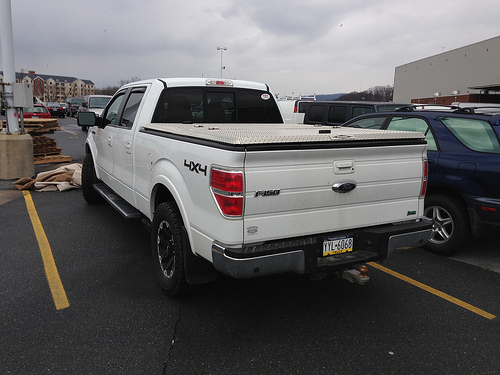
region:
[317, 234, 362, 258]
License plate on pickup truck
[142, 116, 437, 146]
Steel bed cover on pickup truck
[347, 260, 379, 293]
Trailer hitch on pickup truck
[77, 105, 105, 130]
Rearview mirror on pickup truck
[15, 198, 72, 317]
Yellow lines painted on the street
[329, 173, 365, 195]
Manufacturer emblem of a pickup truck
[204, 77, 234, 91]
Third brake light on the pickup truck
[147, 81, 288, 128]
Tinted rear window on a pickup truck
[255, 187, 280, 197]
Model designation on a pickup truck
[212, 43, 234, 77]
Outdoor lighting in the far distance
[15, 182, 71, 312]
Yellow painted line on the ground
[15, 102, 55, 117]
Red colored car in the distance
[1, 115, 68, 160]
Wooden pallets on the ground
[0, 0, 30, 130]
Grey colored light pole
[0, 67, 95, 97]
Light brown, red, and black apartment complex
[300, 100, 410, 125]
Black colored van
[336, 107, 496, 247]
Blue and black colored car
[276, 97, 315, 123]
White colored van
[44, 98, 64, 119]
Black colored car in the distance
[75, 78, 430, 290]
White, black, and silver colored truck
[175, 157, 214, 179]
"4X4" on the truck.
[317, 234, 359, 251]
License plate on the back.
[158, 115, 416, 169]
Cover over the bed.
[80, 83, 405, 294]
The truck is white.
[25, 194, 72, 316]
Yellow line on the ground.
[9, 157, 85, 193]
Tarp in front of the truck.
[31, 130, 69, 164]
Wood on the ground.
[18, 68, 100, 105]
Building in the background.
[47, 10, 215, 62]
Clouds in the sky.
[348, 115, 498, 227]
Blue car next to the truck.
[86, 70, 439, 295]
the truck is a crew cab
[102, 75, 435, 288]
the truck is white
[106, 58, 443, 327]
the truck is not parked in the space correctly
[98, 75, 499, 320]
the truck is a 4 wheel drive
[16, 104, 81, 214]
it appears there is construction material laying on the ground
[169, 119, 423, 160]
the truck has a bed cover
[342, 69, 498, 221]
the vehicle parked beside him is blue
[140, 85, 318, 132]
the windows of the truck are darkly tinted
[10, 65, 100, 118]
an apartment building is in the background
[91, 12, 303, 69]
it is a very dreary, cloudy day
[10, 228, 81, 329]
yellow line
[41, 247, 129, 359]
yellow line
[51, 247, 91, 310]
yellow line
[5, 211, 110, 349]
yellow line